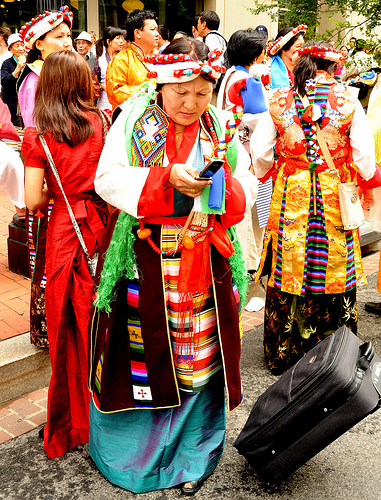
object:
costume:
[83, 95, 245, 493]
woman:
[75, 32, 261, 496]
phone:
[189, 154, 231, 202]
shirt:
[18, 110, 120, 218]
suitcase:
[229, 318, 381, 490]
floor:
[0, 238, 380, 498]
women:
[252, 25, 380, 383]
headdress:
[17, 3, 74, 49]